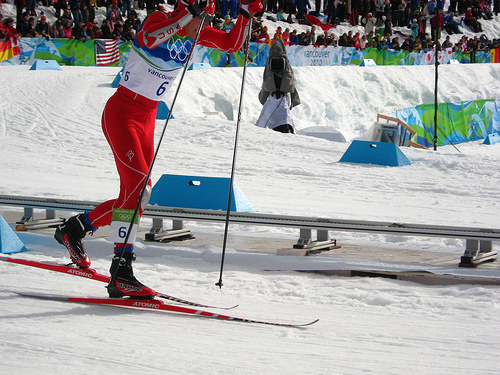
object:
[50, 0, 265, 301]
man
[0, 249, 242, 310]
skis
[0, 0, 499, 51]
crowd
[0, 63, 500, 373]
snow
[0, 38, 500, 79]
wall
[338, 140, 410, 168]
block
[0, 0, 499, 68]
background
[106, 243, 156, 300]
boot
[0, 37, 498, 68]
railing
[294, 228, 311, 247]
support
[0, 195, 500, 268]
track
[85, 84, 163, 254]
pants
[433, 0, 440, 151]
tube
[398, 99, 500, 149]
tarp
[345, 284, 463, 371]
snow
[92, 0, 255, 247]
suit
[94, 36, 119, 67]
flag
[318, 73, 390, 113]
snow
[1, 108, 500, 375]
ground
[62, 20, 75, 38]
people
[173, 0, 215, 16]
helmet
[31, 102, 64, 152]
tracks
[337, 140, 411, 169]
ramp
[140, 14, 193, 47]
arm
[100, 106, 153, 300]
leg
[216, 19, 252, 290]
pole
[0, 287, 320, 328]
ski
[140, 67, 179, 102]
card